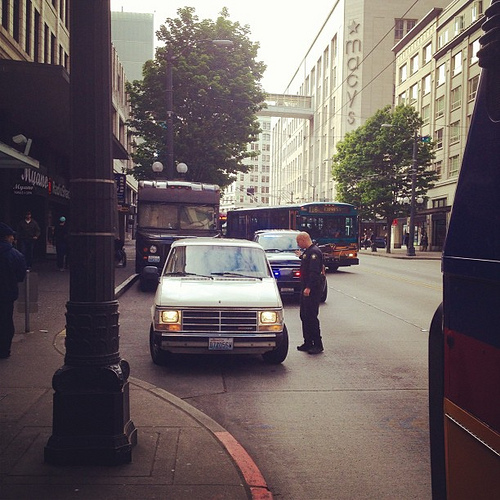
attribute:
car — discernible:
[148, 234, 293, 371]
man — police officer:
[290, 228, 332, 357]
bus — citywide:
[223, 199, 362, 275]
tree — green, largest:
[341, 102, 442, 260]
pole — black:
[163, 30, 238, 179]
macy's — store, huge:
[268, 1, 395, 254]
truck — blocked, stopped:
[130, 174, 230, 297]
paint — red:
[208, 423, 277, 500]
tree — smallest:
[330, 121, 378, 257]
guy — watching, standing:
[2, 223, 33, 365]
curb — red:
[212, 415, 275, 499]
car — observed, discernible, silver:
[247, 225, 332, 306]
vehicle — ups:
[136, 180, 226, 296]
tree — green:
[117, 4, 268, 202]